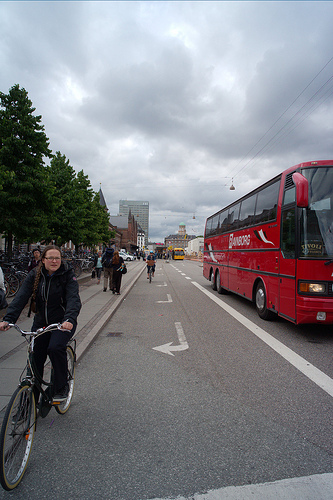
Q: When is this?
A: Daytime.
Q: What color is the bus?
A: Red.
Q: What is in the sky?
A: Clouds.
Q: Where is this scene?
A: In a city.